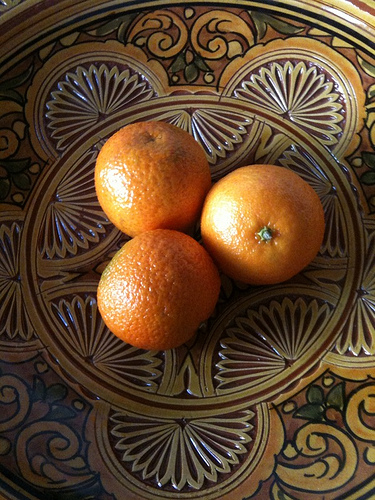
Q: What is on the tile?
A: The group of oranges.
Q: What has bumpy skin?
A: The small orange.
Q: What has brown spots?
A: The orange.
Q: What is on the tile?
A: The curved designs.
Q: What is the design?
A: Peacock feather shaped.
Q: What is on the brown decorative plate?
A: The oranges.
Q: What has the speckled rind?
A: The orange.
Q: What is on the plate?
A: Oranges.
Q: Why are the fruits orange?
A: Because they are ripe.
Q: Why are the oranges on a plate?
A: So they cannot roll away.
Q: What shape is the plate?
A: A circle.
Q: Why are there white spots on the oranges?
A: Light is reflecting off of them.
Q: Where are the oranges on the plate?
A: In the middle.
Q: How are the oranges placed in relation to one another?
A: Touching right next to each other.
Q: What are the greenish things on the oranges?
A: What's left of their stems.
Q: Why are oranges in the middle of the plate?
A: Because the plate's edges are raised.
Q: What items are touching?
A: Oranges.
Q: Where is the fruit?
A: On background.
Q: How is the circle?
A: Decorative.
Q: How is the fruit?
A: Bruised.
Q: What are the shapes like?
A: Ears.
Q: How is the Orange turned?
A: Sideways.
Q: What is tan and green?
A: Paint.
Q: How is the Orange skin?
A: Bumpy.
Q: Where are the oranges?
A: On plate.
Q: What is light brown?
A: Orange.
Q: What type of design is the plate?
A: A peacock feather design.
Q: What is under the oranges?
A: A large brown circle design.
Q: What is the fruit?
A: Orange.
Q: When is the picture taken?
A: Daytime.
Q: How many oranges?
A: 3.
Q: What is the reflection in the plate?
A: Light.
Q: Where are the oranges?
A: In the table.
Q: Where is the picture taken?
A: Above a bowl.